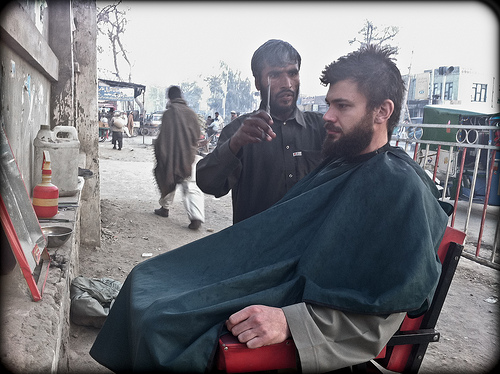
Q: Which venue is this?
A: This is a street.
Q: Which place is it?
A: It is a street.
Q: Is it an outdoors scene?
A: Yes, it is outdoors.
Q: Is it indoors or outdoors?
A: It is outdoors.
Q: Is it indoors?
A: No, it is outdoors.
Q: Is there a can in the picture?
A: Yes, there is a can.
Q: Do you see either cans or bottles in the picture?
A: Yes, there is a can.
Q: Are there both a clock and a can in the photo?
A: No, there is a can but no clocks.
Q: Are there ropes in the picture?
A: No, there are no ropes.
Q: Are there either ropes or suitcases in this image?
A: No, there are no ropes or suitcases.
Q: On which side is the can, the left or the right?
A: The can is on the left of the image.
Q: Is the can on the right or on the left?
A: The can is on the left of the image.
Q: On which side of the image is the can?
A: The can is on the left of the image.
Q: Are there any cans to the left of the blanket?
A: Yes, there is a can to the left of the blanket.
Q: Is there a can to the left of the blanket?
A: Yes, there is a can to the left of the blanket.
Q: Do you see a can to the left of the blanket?
A: Yes, there is a can to the left of the blanket.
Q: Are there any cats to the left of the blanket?
A: No, there is a can to the left of the blanket.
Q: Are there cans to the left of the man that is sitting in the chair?
A: Yes, there is a can to the left of the man.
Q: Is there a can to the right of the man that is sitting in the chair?
A: No, the can is to the left of the man.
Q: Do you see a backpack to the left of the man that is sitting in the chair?
A: No, there is a can to the left of the man.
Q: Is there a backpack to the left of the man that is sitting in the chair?
A: No, there is a can to the left of the man.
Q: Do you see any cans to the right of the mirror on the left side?
A: Yes, there is a can to the right of the mirror.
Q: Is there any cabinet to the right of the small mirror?
A: No, there is a can to the right of the mirror.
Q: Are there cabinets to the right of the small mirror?
A: No, there is a can to the right of the mirror.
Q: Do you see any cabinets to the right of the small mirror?
A: No, there is a can to the right of the mirror.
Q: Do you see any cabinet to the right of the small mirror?
A: No, there is a can to the right of the mirror.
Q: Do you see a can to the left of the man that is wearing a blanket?
A: Yes, there is a can to the left of the man.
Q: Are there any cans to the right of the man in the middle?
A: No, the can is to the left of the man.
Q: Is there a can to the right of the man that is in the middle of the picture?
A: No, the can is to the left of the man.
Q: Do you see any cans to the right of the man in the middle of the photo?
A: No, the can is to the left of the man.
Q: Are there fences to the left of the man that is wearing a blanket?
A: No, there is a can to the left of the man.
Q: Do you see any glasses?
A: No, there are no glasses.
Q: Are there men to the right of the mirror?
A: Yes, there is a man to the right of the mirror.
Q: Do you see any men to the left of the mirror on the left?
A: No, the man is to the right of the mirror.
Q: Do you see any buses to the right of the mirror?
A: No, there is a man to the right of the mirror.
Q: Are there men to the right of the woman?
A: Yes, there is a man to the right of the woman.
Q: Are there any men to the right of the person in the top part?
A: Yes, there is a man to the right of the woman.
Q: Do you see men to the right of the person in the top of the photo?
A: Yes, there is a man to the right of the woman.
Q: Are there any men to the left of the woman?
A: No, the man is to the right of the woman.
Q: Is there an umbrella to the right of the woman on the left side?
A: No, there is a man to the right of the woman.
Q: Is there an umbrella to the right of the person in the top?
A: No, there is a man to the right of the woman.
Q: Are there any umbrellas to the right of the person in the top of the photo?
A: No, there is a man to the right of the woman.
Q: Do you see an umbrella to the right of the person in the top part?
A: No, there is a man to the right of the woman.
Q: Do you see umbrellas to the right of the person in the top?
A: No, there is a man to the right of the woman.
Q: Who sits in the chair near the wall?
A: The man sits in the chair.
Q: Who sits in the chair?
A: The man sits in the chair.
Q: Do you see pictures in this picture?
A: No, there are no pictures.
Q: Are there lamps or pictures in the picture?
A: No, there are no pictures or lamps.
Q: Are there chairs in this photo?
A: Yes, there is a chair.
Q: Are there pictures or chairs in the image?
A: Yes, there is a chair.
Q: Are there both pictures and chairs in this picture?
A: No, there is a chair but no pictures.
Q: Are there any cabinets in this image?
A: No, there are no cabinets.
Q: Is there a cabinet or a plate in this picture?
A: No, there are no cabinets or plates.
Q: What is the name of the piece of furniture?
A: The piece of furniture is a chair.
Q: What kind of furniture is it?
A: The piece of furniture is a chair.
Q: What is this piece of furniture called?
A: This is a chair.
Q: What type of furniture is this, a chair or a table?
A: This is a chair.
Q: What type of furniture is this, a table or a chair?
A: This is a chair.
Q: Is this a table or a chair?
A: This is a chair.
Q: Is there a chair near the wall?
A: Yes, there is a chair near the wall.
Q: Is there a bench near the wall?
A: No, there is a chair near the wall.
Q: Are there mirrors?
A: Yes, there is a mirror.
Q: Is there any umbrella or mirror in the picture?
A: Yes, there is a mirror.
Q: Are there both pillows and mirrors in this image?
A: No, there is a mirror but no pillows.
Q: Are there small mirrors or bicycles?
A: Yes, there is a small mirror.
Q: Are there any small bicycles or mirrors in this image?
A: Yes, there is a small mirror.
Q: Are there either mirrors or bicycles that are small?
A: Yes, the mirror is small.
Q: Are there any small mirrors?
A: Yes, there is a small mirror.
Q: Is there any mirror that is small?
A: Yes, there is a mirror that is small.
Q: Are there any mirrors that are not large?
A: Yes, there is a small mirror.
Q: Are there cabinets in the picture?
A: No, there are no cabinets.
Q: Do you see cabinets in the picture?
A: No, there are no cabinets.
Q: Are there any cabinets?
A: No, there are no cabinets.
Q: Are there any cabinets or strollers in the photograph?
A: No, there are no cabinets or strollers.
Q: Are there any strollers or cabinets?
A: No, there are no cabinets or strollers.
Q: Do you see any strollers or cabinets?
A: No, there are no cabinets or strollers.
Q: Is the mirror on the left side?
A: Yes, the mirror is on the left of the image.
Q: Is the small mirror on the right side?
A: No, the mirror is on the left of the image.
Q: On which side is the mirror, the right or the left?
A: The mirror is on the left of the image.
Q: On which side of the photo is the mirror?
A: The mirror is on the left of the image.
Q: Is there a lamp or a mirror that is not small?
A: No, there is a mirror but it is small.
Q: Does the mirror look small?
A: Yes, the mirror is small.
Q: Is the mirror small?
A: Yes, the mirror is small.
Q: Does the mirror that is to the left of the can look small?
A: Yes, the mirror is small.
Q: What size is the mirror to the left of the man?
A: The mirror is small.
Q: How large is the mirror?
A: The mirror is small.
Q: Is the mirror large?
A: No, the mirror is small.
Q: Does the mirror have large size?
A: No, the mirror is small.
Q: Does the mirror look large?
A: No, the mirror is small.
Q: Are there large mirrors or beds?
A: No, there is a mirror but it is small.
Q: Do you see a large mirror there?
A: No, there is a mirror but it is small.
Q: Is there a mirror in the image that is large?
A: No, there is a mirror but it is small.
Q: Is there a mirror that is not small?
A: No, there is a mirror but it is small.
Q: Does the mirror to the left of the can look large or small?
A: The mirror is small.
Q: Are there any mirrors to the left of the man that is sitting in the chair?
A: Yes, there is a mirror to the left of the man.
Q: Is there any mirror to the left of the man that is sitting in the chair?
A: Yes, there is a mirror to the left of the man.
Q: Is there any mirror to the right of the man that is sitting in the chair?
A: No, the mirror is to the left of the man.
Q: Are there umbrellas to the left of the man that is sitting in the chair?
A: No, there is a mirror to the left of the man.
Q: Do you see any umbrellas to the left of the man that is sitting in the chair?
A: No, there is a mirror to the left of the man.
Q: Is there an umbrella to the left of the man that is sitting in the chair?
A: No, there is a mirror to the left of the man.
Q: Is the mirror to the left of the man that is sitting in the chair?
A: Yes, the mirror is to the left of the man.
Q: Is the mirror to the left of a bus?
A: No, the mirror is to the left of the man.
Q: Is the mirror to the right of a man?
A: No, the mirror is to the left of a man.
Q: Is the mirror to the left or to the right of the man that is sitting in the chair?
A: The mirror is to the left of the man.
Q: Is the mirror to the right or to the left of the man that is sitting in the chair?
A: The mirror is to the left of the man.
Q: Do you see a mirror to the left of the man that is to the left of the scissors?
A: Yes, there is a mirror to the left of the man.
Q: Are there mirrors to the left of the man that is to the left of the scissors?
A: Yes, there is a mirror to the left of the man.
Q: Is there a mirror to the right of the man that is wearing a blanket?
A: No, the mirror is to the left of the man.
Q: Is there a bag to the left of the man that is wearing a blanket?
A: No, there is a mirror to the left of the man.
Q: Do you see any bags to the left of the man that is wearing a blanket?
A: No, there is a mirror to the left of the man.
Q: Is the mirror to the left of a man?
A: Yes, the mirror is to the left of a man.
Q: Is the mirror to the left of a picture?
A: No, the mirror is to the left of a man.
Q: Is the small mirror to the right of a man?
A: No, the mirror is to the left of a man.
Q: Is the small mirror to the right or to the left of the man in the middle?
A: The mirror is to the left of the man.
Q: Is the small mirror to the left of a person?
A: Yes, the mirror is to the left of a person.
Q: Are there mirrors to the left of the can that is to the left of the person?
A: Yes, there is a mirror to the left of the can.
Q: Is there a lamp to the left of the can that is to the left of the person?
A: No, there is a mirror to the left of the can.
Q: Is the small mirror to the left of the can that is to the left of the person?
A: Yes, the mirror is to the left of the can.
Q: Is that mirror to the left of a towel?
A: No, the mirror is to the left of the can.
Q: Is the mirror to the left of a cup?
A: No, the mirror is to the left of the can.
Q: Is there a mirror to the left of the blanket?
A: Yes, there is a mirror to the left of the blanket.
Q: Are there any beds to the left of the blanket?
A: No, there is a mirror to the left of the blanket.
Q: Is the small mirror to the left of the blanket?
A: Yes, the mirror is to the left of the blanket.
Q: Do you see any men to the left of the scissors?
A: Yes, there is a man to the left of the scissors.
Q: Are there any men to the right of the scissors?
A: No, the man is to the left of the scissors.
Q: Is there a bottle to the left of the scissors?
A: No, there is a man to the left of the scissors.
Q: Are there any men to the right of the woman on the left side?
A: Yes, there is a man to the right of the woman.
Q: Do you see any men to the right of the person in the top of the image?
A: Yes, there is a man to the right of the woman.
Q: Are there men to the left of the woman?
A: No, the man is to the right of the woman.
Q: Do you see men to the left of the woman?
A: No, the man is to the right of the woman.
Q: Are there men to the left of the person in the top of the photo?
A: No, the man is to the right of the woman.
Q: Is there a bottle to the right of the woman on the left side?
A: No, there is a man to the right of the woman.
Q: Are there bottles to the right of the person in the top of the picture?
A: No, there is a man to the right of the woman.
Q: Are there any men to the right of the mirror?
A: Yes, there is a man to the right of the mirror.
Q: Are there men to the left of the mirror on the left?
A: No, the man is to the right of the mirror.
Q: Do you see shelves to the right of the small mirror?
A: No, there is a man to the right of the mirror.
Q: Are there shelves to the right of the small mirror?
A: No, there is a man to the right of the mirror.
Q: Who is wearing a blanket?
A: The man is wearing a blanket.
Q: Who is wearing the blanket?
A: The man is wearing a blanket.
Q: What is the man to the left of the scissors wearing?
A: The man is wearing a blanket.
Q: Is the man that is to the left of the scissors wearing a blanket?
A: Yes, the man is wearing a blanket.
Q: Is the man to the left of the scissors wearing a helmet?
A: No, the man is wearing a blanket.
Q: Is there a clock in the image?
A: No, there are no clocks.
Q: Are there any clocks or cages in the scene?
A: No, there are no clocks or cages.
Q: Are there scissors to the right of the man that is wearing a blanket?
A: Yes, there are scissors to the right of the man.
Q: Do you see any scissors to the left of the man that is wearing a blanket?
A: No, the scissors are to the right of the man.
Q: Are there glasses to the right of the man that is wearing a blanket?
A: No, there are scissors to the right of the man.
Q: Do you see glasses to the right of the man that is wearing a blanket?
A: No, there are scissors to the right of the man.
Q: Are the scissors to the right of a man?
A: Yes, the scissors are to the right of a man.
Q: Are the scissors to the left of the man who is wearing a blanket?
A: No, the scissors are to the right of the man.